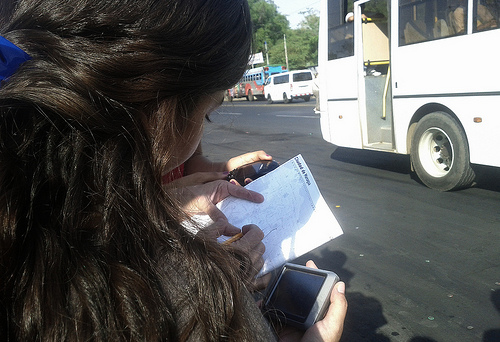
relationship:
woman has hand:
[0, 2, 346, 337] [268, 259, 348, 341]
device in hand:
[260, 262, 340, 342] [268, 259, 348, 341]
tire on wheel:
[408, 110, 479, 192] [316, 0, 498, 192]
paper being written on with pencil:
[167, 150, 343, 288] [221, 230, 245, 247]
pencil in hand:
[220, 230, 249, 245] [201, 215, 263, 287]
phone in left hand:
[198, 157, 323, 187] [221, 149, 273, 188]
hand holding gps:
[268, 259, 348, 341] [263, 258, 334, 338]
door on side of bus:
[356, 0, 394, 152] [334, 0, 490, 158]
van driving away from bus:
[260, 67, 315, 103] [295, 8, 498, 216]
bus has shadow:
[312, 5, 498, 187] [330, 147, 499, 192]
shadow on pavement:
[330, 147, 499, 192] [197, 102, 498, 340]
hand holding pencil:
[197, 224, 266, 279] [214, 230, 246, 245]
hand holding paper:
[164, 177, 263, 224] [178, 153, 344, 277]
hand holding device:
[268, 259, 346, 340] [258, 262, 341, 331]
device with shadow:
[258, 262, 341, 331] [321, 248, 385, 342]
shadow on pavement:
[321, 248, 385, 342] [197, 102, 498, 340]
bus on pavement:
[312, 5, 498, 187] [200, 100, 500, 342]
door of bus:
[355, 3, 412, 156] [303, 2, 480, 198]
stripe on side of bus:
[327, 90, 499, 101] [312, 5, 498, 187]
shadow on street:
[292, 248, 498, 340] [101, 35, 485, 293]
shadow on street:
[330, 147, 499, 192] [101, 35, 485, 293]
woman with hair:
[0, 2, 346, 337] [45, 110, 167, 301]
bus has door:
[312, 5, 498, 187] [352, 1, 399, 150]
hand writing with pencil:
[190, 212, 275, 291] [216, 228, 248, 248]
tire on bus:
[410, 111, 477, 192] [312, 5, 498, 187]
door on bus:
[356, 0, 394, 152] [312, 5, 498, 187]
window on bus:
[327, 0, 353, 62] [312, 5, 498, 187]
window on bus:
[324, 0, 357, 62] [312, 5, 498, 187]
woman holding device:
[0, 2, 346, 337] [257, 255, 341, 332]